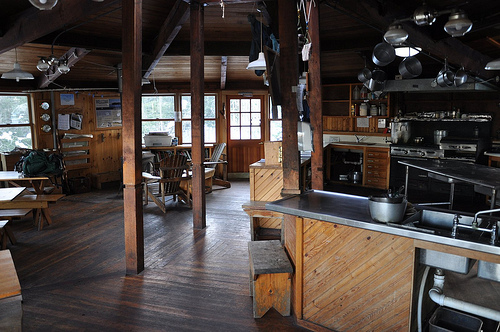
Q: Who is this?
A: No one.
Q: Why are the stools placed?
A: To be sat on.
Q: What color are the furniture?
A: Brown.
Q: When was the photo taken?
A: Daytime.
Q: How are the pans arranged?
A: On the room.